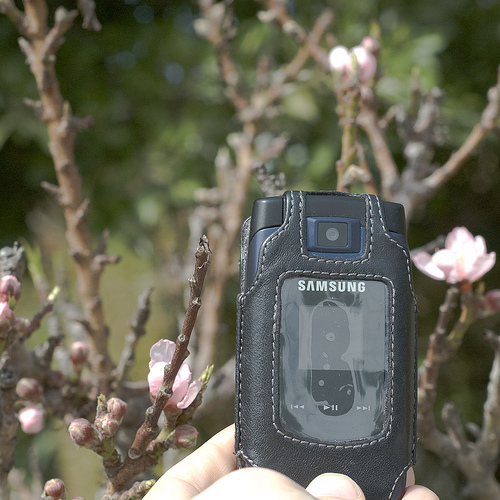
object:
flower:
[409, 225, 496, 285]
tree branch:
[415, 276, 499, 498]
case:
[233, 190, 417, 500]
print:
[296, 279, 366, 293]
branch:
[68, 235, 215, 499]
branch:
[357, 52, 497, 227]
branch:
[0, 0, 115, 365]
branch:
[184, 2, 336, 397]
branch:
[111, 283, 155, 388]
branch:
[8, 285, 61, 351]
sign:
[323, 404, 338, 411]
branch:
[108, 285, 153, 398]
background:
[1, 0, 499, 498]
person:
[140, 423, 441, 500]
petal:
[463, 249, 498, 281]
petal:
[474, 234, 484, 260]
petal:
[432, 248, 460, 279]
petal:
[407, 249, 439, 276]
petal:
[447, 225, 470, 251]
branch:
[410, 226, 496, 421]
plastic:
[275, 274, 392, 441]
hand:
[142, 423, 439, 500]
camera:
[306, 216, 361, 253]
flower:
[147, 338, 202, 409]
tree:
[0, 0, 500, 500]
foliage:
[68, 26, 199, 220]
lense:
[317, 222, 348, 247]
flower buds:
[68, 341, 89, 365]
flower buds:
[18, 404, 45, 435]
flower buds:
[1, 274, 21, 304]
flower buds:
[0, 301, 13, 329]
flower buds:
[15, 378, 44, 401]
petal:
[146, 339, 210, 411]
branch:
[192, 1, 334, 378]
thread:
[234, 190, 418, 498]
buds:
[68, 393, 128, 449]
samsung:
[297, 279, 366, 292]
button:
[323, 404, 338, 411]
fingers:
[146, 422, 441, 500]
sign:
[356, 405, 371, 411]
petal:
[329, 45, 356, 87]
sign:
[290, 403, 304, 409]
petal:
[177, 381, 199, 411]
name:
[297, 279, 366, 293]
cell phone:
[234, 190, 417, 499]